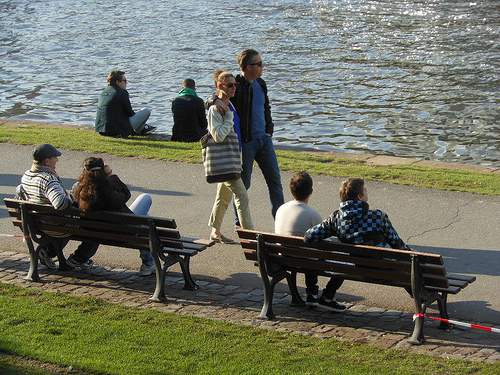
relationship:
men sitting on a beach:
[272, 164, 403, 309] [239, 231, 478, 341]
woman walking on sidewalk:
[193, 67, 258, 251] [6, 141, 500, 332]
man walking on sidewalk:
[233, 50, 293, 220] [6, 141, 500, 332]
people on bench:
[70, 156, 170, 276] [7, 201, 212, 300]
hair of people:
[79, 169, 110, 206] [70, 156, 170, 276]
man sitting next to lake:
[168, 82, 204, 136] [1, 4, 495, 159]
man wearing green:
[168, 82, 204, 136] [177, 90, 200, 97]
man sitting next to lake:
[98, 68, 152, 137] [1, 4, 495, 159]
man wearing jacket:
[98, 68, 152, 137] [102, 86, 133, 135]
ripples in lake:
[27, 13, 499, 124] [1, 4, 495, 159]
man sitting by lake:
[168, 82, 204, 136] [1, 4, 495, 159]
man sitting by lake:
[98, 68, 152, 137] [1, 4, 495, 159]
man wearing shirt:
[233, 50, 293, 220] [248, 83, 265, 135]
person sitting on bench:
[25, 148, 96, 265] [7, 201, 212, 300]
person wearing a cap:
[25, 148, 96, 265] [35, 143, 63, 157]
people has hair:
[70, 156, 170, 276] [79, 169, 110, 206]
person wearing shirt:
[280, 180, 349, 309] [272, 205, 324, 236]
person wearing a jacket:
[25, 148, 96, 265] [22, 168, 69, 233]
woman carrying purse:
[193, 67, 258, 251] [200, 102, 242, 178]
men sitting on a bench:
[272, 164, 403, 309] [239, 231, 458, 332]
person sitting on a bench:
[25, 148, 96, 265] [7, 201, 212, 300]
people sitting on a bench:
[70, 156, 170, 276] [7, 201, 212, 300]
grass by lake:
[3, 120, 498, 195] [1, 4, 495, 159]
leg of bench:
[259, 273, 278, 319] [7, 201, 212, 300]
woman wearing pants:
[193, 67, 258, 251] [209, 176, 248, 239]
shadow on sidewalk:
[4, 164, 185, 215] [6, 141, 500, 332]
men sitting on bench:
[272, 164, 403, 309] [239, 231, 458, 332]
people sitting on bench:
[15, 140, 162, 273] [7, 201, 212, 300]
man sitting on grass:
[168, 82, 204, 136] [3, 120, 498, 195]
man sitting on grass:
[98, 68, 152, 137] [3, 120, 498, 195]